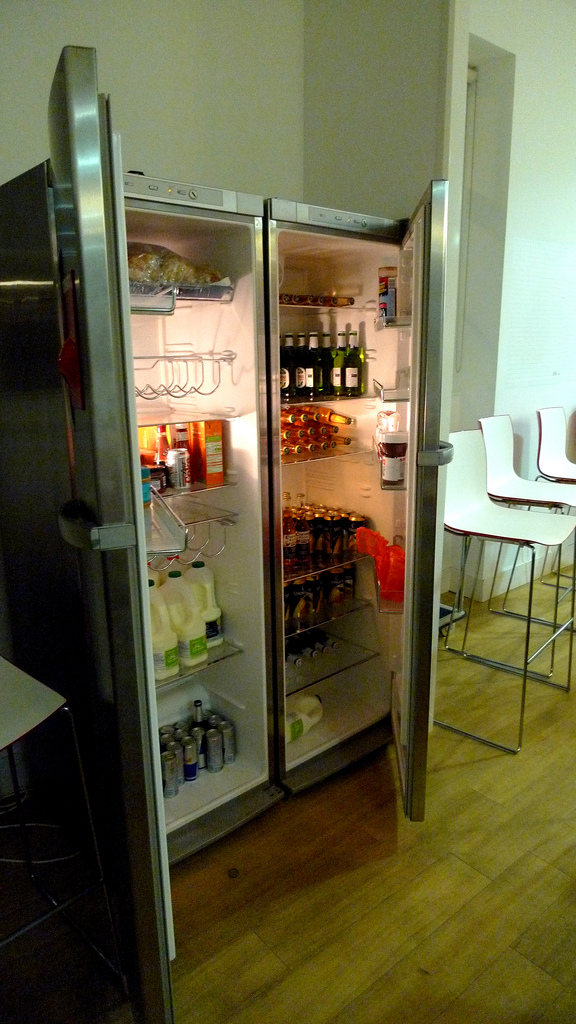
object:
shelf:
[156, 723, 265, 825]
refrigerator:
[4, 140, 465, 956]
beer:
[280, 320, 366, 400]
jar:
[378, 430, 407, 487]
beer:
[159, 699, 236, 797]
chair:
[539, 406, 576, 589]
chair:
[443, 414, 576, 676]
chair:
[434, 429, 576, 758]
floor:
[167, 569, 576, 1023]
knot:
[228, 868, 239, 877]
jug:
[285, 695, 322, 745]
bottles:
[279, 293, 354, 306]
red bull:
[204, 733, 225, 772]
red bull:
[161, 751, 175, 795]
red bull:
[220, 723, 237, 762]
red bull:
[179, 737, 197, 778]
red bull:
[167, 742, 186, 781]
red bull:
[206, 726, 224, 772]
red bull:
[183, 736, 198, 780]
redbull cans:
[159, 710, 237, 797]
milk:
[184, 561, 224, 649]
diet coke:
[167, 447, 191, 490]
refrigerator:
[2, 46, 450, 1023]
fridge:
[3, 46, 454, 1023]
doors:
[47, 39, 452, 1024]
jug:
[148, 561, 224, 681]